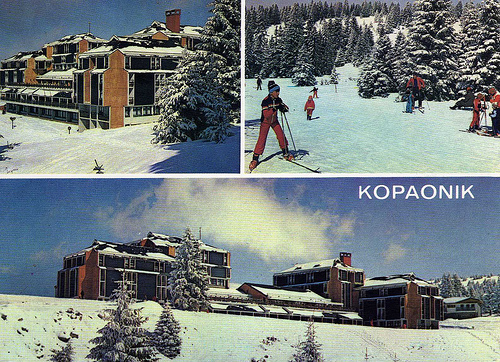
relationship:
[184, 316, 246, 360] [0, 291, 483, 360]
snow covered ground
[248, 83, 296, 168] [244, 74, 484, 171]
boy skiing up hill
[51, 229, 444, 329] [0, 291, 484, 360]
lodge on hill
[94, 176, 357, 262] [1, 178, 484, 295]
clouds in sky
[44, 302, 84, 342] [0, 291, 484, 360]
rocks on hill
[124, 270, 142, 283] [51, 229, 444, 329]
windows of lodge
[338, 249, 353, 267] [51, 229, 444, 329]
chimney of lodge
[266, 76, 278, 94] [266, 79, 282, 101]
hat on a head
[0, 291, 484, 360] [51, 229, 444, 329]
hill in front of lodge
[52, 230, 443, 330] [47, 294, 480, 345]
building in snow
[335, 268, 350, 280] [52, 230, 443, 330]
window on building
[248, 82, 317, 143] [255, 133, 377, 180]
boy on skis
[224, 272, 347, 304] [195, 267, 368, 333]
roof on building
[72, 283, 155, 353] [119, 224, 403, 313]
tree by building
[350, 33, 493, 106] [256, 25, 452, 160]
tree on hill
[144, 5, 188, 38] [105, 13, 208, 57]
chimney on roof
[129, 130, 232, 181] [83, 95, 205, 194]
shadow on snow